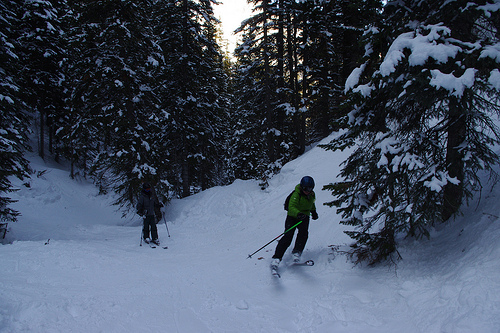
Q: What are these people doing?
A: Cross country skiing.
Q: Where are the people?
A: Wooded area.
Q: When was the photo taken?
A: Winter day.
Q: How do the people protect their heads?
A: Helmets.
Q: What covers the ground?
A: Snow.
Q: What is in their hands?
A: Ski poles.